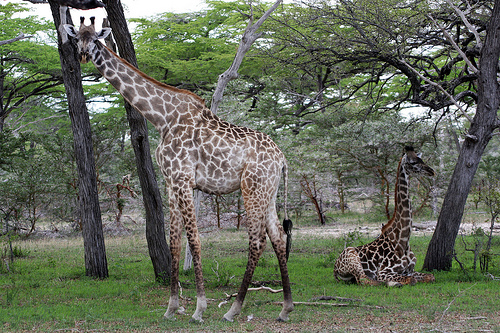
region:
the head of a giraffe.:
[50, 10, 122, 85]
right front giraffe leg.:
[148, 289, 185, 331]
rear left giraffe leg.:
[248, 276, 306, 331]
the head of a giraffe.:
[388, 126, 449, 183]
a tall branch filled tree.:
[405, 0, 497, 304]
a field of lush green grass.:
[3, 234, 498, 331]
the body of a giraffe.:
[155, 87, 281, 187]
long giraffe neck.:
[90, 41, 199, 134]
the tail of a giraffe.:
[270, 137, 310, 243]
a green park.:
[14, 184, 498, 241]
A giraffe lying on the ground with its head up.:
[332, 142, 437, 287]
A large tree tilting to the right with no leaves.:
[275, 0, 498, 272]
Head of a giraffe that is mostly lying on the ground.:
[401, 141, 435, 178]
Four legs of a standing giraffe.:
[154, 175, 295, 325]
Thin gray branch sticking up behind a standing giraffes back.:
[210, 0, 285, 119]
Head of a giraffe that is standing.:
[64, 15, 114, 65]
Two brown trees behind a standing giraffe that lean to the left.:
[46, 0, 177, 285]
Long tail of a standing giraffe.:
[280, 158, 292, 263]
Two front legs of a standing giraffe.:
[158, 171, 208, 327]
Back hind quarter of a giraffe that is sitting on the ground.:
[333, 244, 385, 288]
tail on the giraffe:
[282, 165, 293, 224]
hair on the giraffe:
[125, 59, 171, 86]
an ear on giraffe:
[101, 25, 118, 37]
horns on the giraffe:
[81, 15, 96, 25]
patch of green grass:
[25, 272, 115, 303]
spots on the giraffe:
[209, 134, 256, 177]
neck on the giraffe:
[109, 70, 164, 138]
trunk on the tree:
[430, 187, 458, 270]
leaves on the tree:
[163, 43, 223, 77]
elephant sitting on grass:
[337, 143, 429, 295]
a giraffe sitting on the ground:
[323, 122, 456, 306]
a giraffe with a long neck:
[376, 137, 441, 264]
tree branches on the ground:
[216, 277, 353, 319]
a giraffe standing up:
[54, 20, 307, 331]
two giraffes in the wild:
[3, 5, 471, 327]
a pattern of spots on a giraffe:
[143, 139, 273, 179]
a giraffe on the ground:
[318, 131, 445, 298]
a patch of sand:
[276, 208, 388, 256]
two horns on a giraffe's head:
[52, 15, 118, 70]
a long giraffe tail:
[254, 140, 312, 255]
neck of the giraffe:
[105, 62, 160, 104]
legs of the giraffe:
[151, 226, 312, 301]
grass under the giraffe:
[306, 267, 328, 288]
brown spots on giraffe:
[181, 125, 226, 160]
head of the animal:
[392, 140, 443, 188]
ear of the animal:
[97, 26, 115, 43]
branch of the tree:
[429, 162, 496, 233]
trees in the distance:
[313, 149, 370, 187]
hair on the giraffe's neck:
[118, 54, 196, 97]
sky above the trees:
[142, 4, 174, 17]